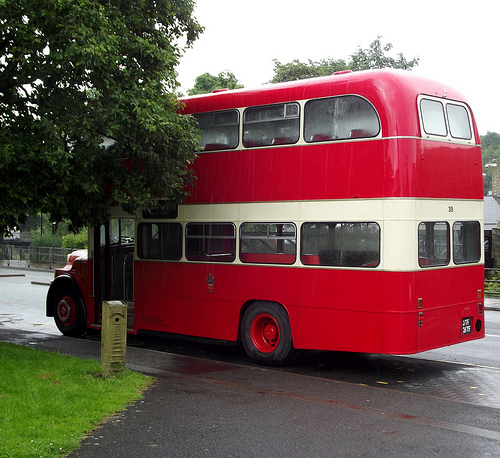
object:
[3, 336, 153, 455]
grass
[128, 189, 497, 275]
band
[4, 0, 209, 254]
tree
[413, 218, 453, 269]
window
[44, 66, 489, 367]
bus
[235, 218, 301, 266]
window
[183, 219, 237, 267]
window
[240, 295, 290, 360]
tire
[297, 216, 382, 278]
window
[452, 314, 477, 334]
license plate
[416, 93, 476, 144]
back window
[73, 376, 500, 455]
pavement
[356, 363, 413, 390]
brick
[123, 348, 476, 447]
street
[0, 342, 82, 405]
patch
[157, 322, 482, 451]
sidewalk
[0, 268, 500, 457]
roadway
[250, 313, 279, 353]
hubcap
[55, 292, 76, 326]
hubcap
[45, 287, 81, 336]
tire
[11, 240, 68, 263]
section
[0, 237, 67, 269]
fencing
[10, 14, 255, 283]
tree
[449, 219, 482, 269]
window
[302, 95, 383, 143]
window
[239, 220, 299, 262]
window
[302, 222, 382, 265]
window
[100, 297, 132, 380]
pole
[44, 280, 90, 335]
wheel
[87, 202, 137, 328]
entrance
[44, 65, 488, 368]
tour bus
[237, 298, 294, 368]
tire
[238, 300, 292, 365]
back wheel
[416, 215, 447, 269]
window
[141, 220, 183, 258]
window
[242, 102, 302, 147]
window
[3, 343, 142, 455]
area